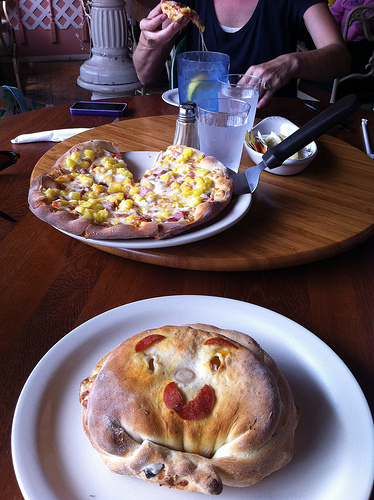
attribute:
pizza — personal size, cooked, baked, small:
[28, 139, 234, 241]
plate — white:
[57, 150, 256, 249]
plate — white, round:
[10, 294, 372, 500]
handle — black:
[260, 93, 365, 170]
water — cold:
[195, 120, 246, 175]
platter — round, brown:
[29, 112, 372, 272]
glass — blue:
[175, 51, 231, 116]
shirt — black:
[186, 1, 330, 98]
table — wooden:
[1, 93, 373, 499]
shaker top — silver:
[177, 101, 198, 124]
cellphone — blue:
[70, 100, 130, 116]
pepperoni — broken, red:
[163, 382, 221, 420]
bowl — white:
[246, 115, 317, 177]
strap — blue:
[3, 84, 29, 112]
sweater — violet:
[330, 0, 374, 41]